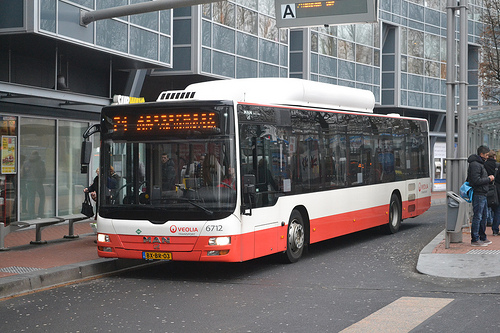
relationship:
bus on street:
[60, 75, 457, 282] [83, 233, 428, 326]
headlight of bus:
[207, 236, 228, 245] [90, 76, 435, 265]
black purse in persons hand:
[81, 191, 94, 215] [82, 186, 87, 191]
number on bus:
[205, 224, 223, 232] [90, 76, 435, 265]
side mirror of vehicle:
[80, 121, 95, 174] [77, 67, 436, 263]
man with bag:
[466, 145, 495, 247] [457, 182, 471, 199]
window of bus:
[241, 104, 431, 209] [90, 76, 435, 265]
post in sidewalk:
[434, 0, 485, 260] [398, 219, 499, 276]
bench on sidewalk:
[57, 211, 87, 241] [0, 215, 112, 297]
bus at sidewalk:
[90, 76, 435, 265] [414, 210, 497, 289]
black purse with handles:
[80, 191, 95, 218] [82, 189, 92, 203]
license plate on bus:
[142, 251, 173, 260] [74, 84, 466, 279]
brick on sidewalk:
[41, 246, 68, 261] [0, 217, 100, 274]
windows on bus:
[238, 111, 433, 198] [94, 99, 436, 261]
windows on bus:
[108, 145, 233, 215] [94, 99, 436, 261]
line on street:
[338, 296, 455, 329] [0, 201, 500, 331]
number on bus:
[200, 221, 227, 236] [92, 54, 434, 269]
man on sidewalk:
[466, 145, 495, 247] [434, 223, 497, 265]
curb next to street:
[0, 258, 154, 292] [0, 201, 500, 331]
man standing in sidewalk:
[466, 147, 498, 248] [386, 236, 480, 313]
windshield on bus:
[75, 113, 237, 216] [90, 76, 435, 265]